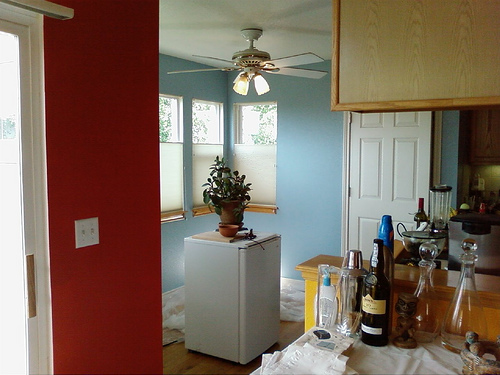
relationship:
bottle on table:
[358, 241, 393, 347] [247, 315, 498, 375]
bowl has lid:
[403, 231, 448, 263] [402, 231, 447, 239]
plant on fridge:
[202, 156, 253, 231] [186, 228, 281, 364]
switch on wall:
[73, 216, 100, 250] [44, 2, 165, 375]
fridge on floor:
[186, 228, 281, 364] [163, 275, 304, 374]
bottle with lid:
[378, 214, 395, 339] [378, 215, 395, 255]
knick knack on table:
[394, 292, 418, 349] [247, 315, 498, 375]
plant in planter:
[202, 156, 253, 231] [219, 196, 244, 229]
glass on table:
[442, 238, 491, 355] [247, 315, 498, 375]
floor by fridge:
[163, 275, 304, 374] [186, 228, 281, 364]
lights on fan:
[234, 70, 271, 98] [167, 28, 328, 95]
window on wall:
[192, 97, 225, 215] [158, 53, 342, 296]